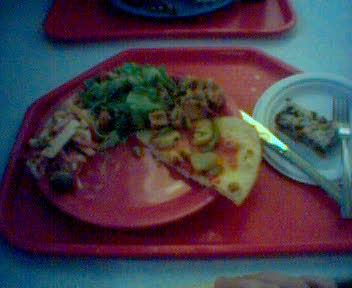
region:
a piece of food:
[38, 46, 259, 271]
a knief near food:
[231, 109, 317, 180]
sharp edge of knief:
[236, 106, 295, 161]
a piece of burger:
[138, 121, 282, 217]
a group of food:
[26, 64, 217, 176]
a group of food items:
[17, 68, 242, 198]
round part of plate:
[91, 187, 193, 237]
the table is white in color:
[310, 11, 341, 48]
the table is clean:
[306, 14, 338, 50]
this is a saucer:
[309, 75, 323, 95]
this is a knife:
[245, 100, 338, 208]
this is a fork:
[330, 95, 351, 236]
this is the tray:
[263, 210, 296, 235]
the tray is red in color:
[272, 183, 303, 219]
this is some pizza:
[111, 79, 256, 197]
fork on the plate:
[326, 96, 350, 228]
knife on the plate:
[240, 104, 350, 213]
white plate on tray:
[253, 64, 350, 189]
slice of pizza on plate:
[144, 116, 262, 212]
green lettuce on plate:
[106, 74, 152, 118]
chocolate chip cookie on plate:
[276, 99, 334, 145]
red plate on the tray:
[22, 69, 246, 248]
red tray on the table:
[1, 38, 347, 267]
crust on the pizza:
[226, 118, 258, 204]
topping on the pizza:
[191, 149, 217, 169]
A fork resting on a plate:
[329, 91, 351, 180]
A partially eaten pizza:
[51, 77, 254, 221]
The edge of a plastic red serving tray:
[61, 228, 281, 271]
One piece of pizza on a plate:
[140, 120, 269, 196]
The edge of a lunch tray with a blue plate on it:
[46, 2, 301, 45]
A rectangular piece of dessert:
[271, 108, 346, 152]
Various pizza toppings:
[39, 112, 91, 162]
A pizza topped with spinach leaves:
[88, 64, 184, 126]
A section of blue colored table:
[78, 260, 181, 285]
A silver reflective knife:
[237, 112, 310, 167]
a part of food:
[36, 45, 351, 266]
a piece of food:
[147, 125, 281, 221]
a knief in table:
[215, 101, 350, 219]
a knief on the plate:
[232, 113, 346, 199]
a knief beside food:
[230, 99, 314, 196]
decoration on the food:
[176, 112, 239, 170]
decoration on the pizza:
[143, 79, 265, 206]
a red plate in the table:
[37, 229, 147, 270]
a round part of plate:
[92, 198, 161, 229]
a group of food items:
[39, 81, 253, 213]